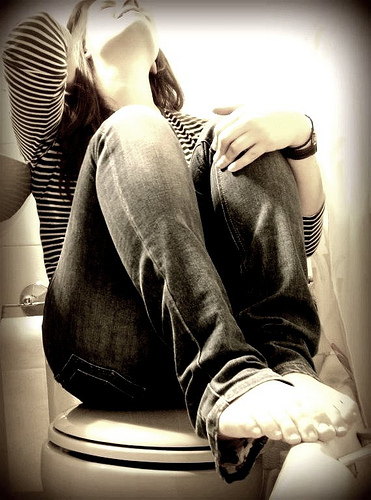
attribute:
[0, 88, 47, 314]
wall — tile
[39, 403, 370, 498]
toilet — white